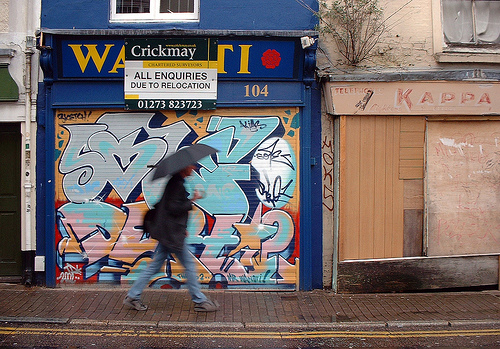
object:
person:
[126, 139, 223, 316]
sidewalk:
[0, 281, 499, 348]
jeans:
[128, 240, 206, 301]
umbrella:
[152, 142, 222, 199]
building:
[34, 0, 323, 290]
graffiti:
[57, 105, 299, 290]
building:
[317, 0, 500, 291]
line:
[5, 323, 500, 339]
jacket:
[149, 180, 190, 253]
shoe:
[194, 297, 221, 311]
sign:
[124, 38, 222, 110]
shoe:
[123, 291, 150, 311]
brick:
[344, 300, 363, 312]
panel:
[432, 3, 500, 65]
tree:
[311, 0, 401, 69]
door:
[424, 120, 499, 258]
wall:
[323, 73, 500, 289]